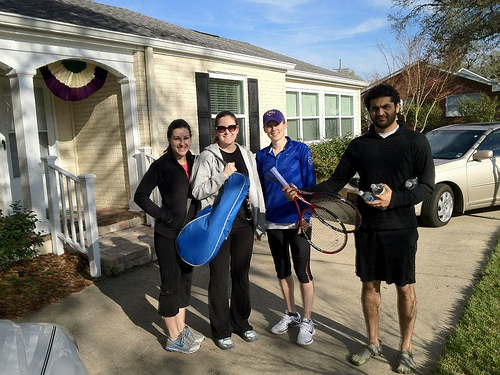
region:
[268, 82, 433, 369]
a man holding tennis rackets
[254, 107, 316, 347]
a woman standing on driveway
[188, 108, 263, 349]
a woman standing on driveway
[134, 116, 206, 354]
a woman standing on driveway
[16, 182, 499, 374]
a paved home driveway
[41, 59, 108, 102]
red white and blue bunting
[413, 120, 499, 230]
a parked gold car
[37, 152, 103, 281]
a white hand railing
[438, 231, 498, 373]
a patch of green grass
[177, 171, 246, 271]
a blue tennis racket bag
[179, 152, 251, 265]
A blue tennis bag.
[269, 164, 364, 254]
Two tennis rackets .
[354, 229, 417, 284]
A pair of black sports shorts.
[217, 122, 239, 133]
A black framed pair of sunglasses.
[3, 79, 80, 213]
A white front door of a house.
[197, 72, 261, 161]
Black shutters on the house.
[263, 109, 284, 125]
A purple ball cap.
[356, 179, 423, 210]
Bottles of water.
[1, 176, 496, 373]
A driveway of a house.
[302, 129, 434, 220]
A long sleeved black shirt.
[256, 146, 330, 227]
the top is blue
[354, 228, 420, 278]
the shorts are black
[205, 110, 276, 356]
the guy has glasses on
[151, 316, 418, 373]
they have sport shoes on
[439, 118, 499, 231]
the car is silver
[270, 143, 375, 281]
the tennis rackets are two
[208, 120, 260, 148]
she has sungllasses on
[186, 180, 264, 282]
the tennis bag is blue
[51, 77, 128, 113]
the object is purple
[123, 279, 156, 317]
shadows are on the ground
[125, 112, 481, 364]
tennis players in a group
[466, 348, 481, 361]
patch of green grass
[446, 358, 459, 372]
patch of green grass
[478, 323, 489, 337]
patch of green grass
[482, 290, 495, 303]
patch of green grass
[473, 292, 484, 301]
patch of green grass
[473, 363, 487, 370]
patch of green grass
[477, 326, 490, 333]
patch of green grass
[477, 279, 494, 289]
patch of green grass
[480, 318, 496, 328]
patch of green grass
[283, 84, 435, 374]
A man in a black outfit.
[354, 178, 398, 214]
The man is holding two water bottles.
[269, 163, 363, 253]
The man is holding two tennis racketts.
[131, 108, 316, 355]
A group of 3 women.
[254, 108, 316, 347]
A woman wearing a blue cap.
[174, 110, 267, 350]
A woman carrying a blue bag.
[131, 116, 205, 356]
A woman in a black outfit.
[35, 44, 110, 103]
A red, white and blue banner is hanging above the door.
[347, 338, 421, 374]
The man is wearing sandals.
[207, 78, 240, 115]
There are blinds in the window.